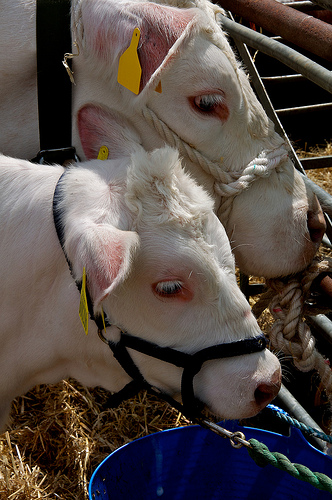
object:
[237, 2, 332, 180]
net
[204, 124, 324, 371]
court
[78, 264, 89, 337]
tag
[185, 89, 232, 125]
eye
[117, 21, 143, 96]
yelllow tag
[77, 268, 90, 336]
yelllow tag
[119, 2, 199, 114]
ear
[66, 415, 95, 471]
top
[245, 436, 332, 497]
rope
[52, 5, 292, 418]
tennis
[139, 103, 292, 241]
rope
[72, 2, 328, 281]
head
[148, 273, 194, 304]
pink circle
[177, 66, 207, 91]
wall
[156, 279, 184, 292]
eyelashes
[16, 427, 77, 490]
grass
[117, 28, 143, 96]
tag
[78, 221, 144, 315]
ear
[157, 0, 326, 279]
face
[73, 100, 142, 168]
ear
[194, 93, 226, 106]
eyelashes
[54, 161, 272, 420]
straps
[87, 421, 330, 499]
bucket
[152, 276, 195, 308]
eye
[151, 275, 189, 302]
ring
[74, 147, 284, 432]
head